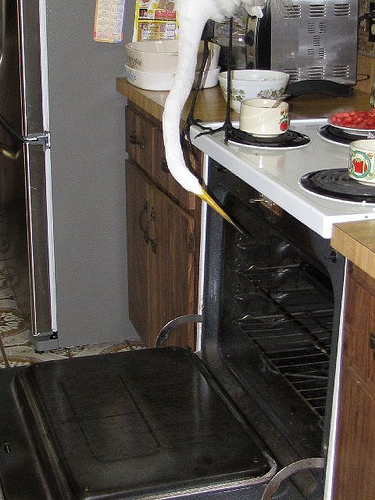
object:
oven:
[0, 108, 373, 499]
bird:
[162, 0, 264, 237]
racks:
[241, 257, 301, 274]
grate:
[233, 252, 330, 423]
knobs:
[245, 28, 255, 44]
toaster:
[208, 1, 359, 80]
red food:
[331, 105, 374, 127]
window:
[18, 335, 269, 467]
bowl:
[217, 69, 291, 115]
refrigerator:
[0, 0, 175, 352]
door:
[23, 346, 272, 499]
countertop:
[330, 220, 373, 277]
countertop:
[115, 76, 373, 127]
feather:
[178, 2, 234, 16]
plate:
[326, 121, 375, 135]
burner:
[317, 124, 373, 147]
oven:
[215, 0, 357, 98]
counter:
[188, 120, 375, 221]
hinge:
[259, 458, 332, 500]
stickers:
[133, 2, 179, 42]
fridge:
[1, 0, 141, 354]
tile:
[0, 340, 72, 367]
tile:
[0, 295, 30, 342]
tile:
[0, 259, 15, 300]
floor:
[1, 204, 149, 378]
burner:
[226, 125, 309, 149]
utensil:
[272, 93, 291, 108]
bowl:
[239, 97, 291, 138]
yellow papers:
[132, 0, 179, 43]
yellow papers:
[92, 0, 125, 44]